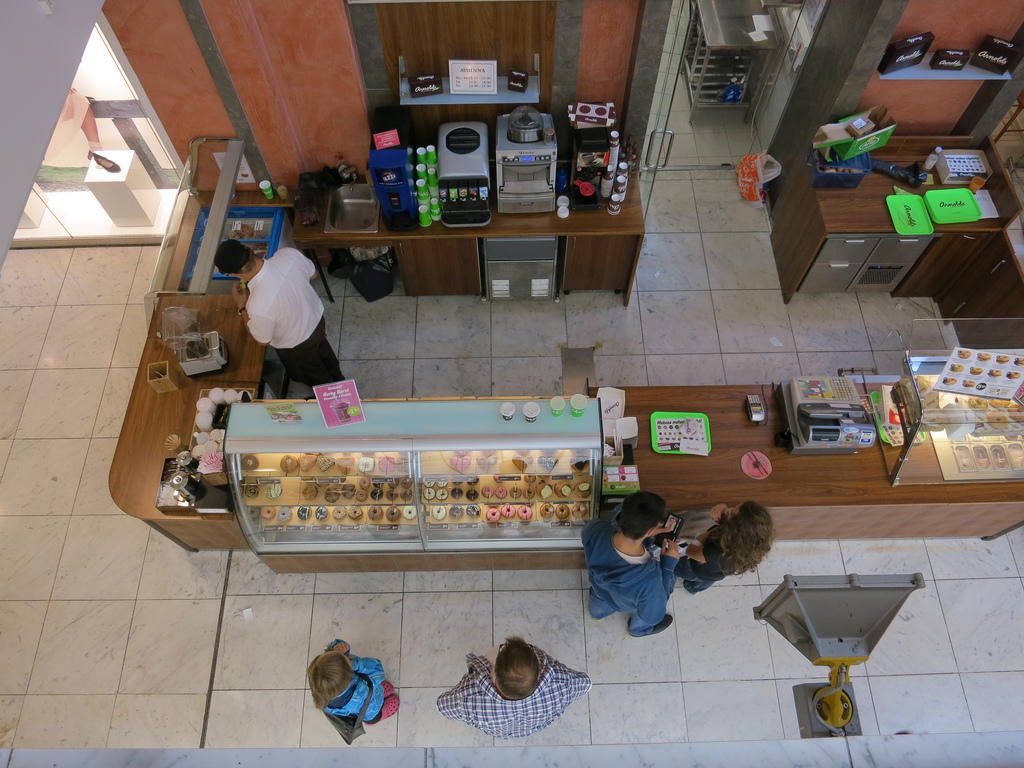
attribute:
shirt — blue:
[321, 635, 429, 728]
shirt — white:
[220, 238, 335, 364]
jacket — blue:
[568, 510, 687, 636]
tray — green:
[879, 184, 938, 249]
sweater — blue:
[559, 508, 691, 640]